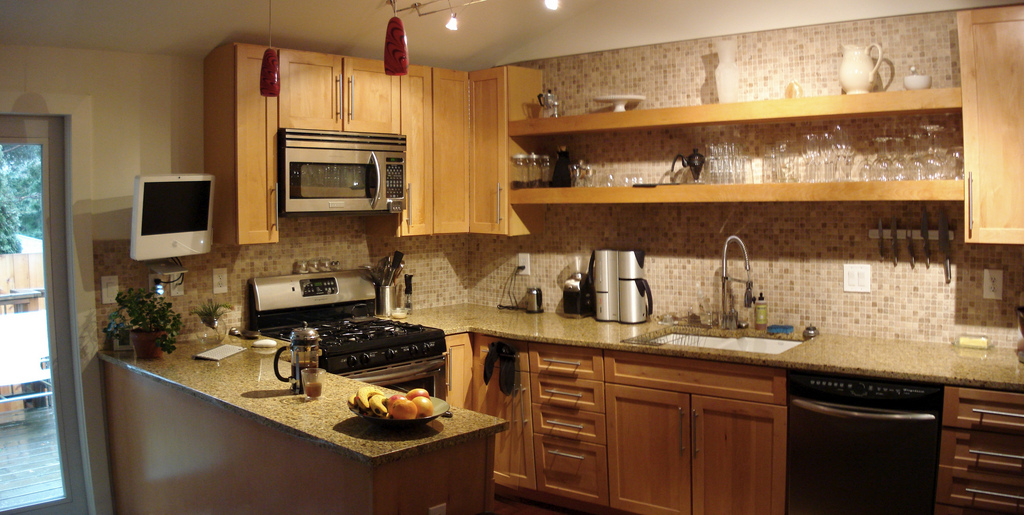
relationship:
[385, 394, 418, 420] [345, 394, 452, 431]
orange in bowl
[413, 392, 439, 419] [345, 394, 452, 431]
orange in bowl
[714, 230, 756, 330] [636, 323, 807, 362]
faucet hanging over sink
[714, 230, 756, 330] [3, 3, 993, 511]
faucet sitting inside kitchen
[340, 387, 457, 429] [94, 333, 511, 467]
basket sitting on top of counter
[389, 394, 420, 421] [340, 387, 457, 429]
fruit lying on top of basket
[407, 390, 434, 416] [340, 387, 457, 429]
fruit lying on top of basket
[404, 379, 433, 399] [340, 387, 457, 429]
fruit lying on top of basket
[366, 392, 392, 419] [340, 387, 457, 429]
fruit lying on top of basket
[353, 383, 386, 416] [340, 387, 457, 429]
fruit lying on top of basket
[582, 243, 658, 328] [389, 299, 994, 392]
coffee maker sitting on top of counter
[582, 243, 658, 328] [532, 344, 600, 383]
coffee maker standing above drawer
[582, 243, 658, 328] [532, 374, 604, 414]
coffee maker standing above drawer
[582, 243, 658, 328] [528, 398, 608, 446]
coffee maker standing above drawer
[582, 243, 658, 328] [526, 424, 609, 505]
coffee maker standing above drawer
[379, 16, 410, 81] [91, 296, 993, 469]
lamp shade hanging above counter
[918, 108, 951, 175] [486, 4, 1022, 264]
glass on shelf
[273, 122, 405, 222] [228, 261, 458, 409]
microwave above stove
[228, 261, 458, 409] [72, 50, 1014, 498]
stove in kitchen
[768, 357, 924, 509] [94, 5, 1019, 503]
dishwasher in kitchen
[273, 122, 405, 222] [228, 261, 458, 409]
microwave hanging above stove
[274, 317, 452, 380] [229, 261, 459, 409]
burners on stove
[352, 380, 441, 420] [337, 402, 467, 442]
fruits on bowl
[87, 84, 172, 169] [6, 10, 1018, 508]
wall in building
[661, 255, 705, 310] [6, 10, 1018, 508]
wall in building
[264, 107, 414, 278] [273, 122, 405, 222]
one black and stainless steel microwave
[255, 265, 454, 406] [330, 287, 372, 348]
one black and stainless steel gas stovetop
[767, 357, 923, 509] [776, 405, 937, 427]
dishwasher with silver handle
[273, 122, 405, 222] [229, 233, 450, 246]
microwave sandwiched between wooden drawers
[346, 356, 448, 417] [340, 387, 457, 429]
bananas and oranges on wide basket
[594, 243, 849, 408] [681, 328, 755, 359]
white colored kitchen sink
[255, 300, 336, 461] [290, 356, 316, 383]
juice in small glass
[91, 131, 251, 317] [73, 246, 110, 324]
screen mounted on wall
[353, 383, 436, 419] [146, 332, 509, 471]
fruit on counter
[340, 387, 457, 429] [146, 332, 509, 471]
basket on counter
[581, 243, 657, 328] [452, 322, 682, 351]
coffee maker on counter top